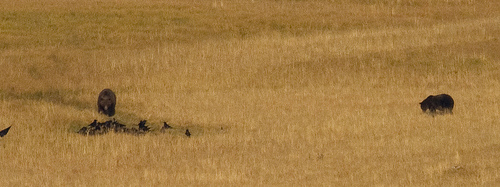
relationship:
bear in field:
[94, 81, 118, 119] [0, 0, 499, 185]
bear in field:
[418, 90, 453, 112] [0, 0, 499, 185]